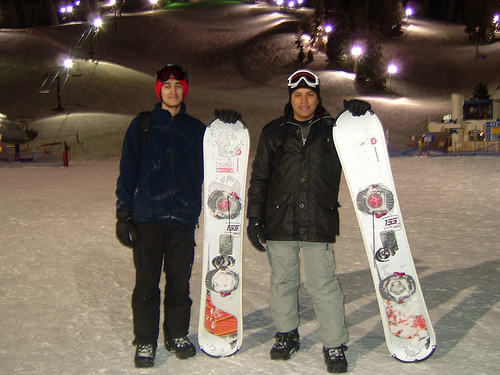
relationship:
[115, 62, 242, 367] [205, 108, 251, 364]
man holding snowboard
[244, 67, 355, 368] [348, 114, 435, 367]
man holding snowboard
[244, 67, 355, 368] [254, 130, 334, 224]
man wearing coat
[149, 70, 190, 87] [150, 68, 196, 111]
hat on top of head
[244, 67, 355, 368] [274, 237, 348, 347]
man wearing pants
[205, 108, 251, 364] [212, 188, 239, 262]
snowboard have decals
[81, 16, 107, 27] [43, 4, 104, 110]
lights on slope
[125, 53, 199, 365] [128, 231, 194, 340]
man wearing pant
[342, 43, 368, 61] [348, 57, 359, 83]
light on pole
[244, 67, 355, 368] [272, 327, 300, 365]
man wearing shoe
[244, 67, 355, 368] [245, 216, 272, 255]
man wearing gloves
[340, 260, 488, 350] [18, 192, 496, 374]
shadow on ground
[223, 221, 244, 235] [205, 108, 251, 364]
155 written on snowboard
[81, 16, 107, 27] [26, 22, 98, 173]
lights on slopes